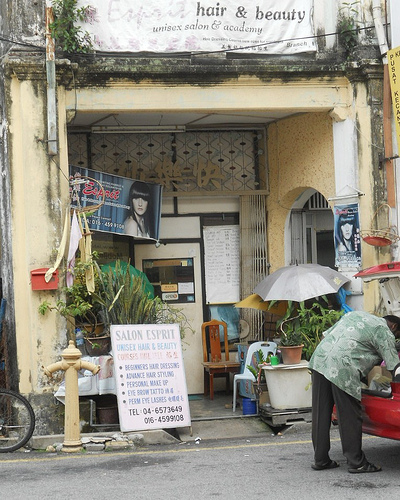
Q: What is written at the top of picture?
A: Hair & Beauty.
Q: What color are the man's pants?
A: Gray.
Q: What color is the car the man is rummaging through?
A: Red.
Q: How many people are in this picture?
A: 1.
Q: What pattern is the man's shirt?
A: Flowers.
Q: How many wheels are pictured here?
A: 1.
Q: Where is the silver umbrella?
A: In front of the doorway.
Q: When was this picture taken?
A: Daytime.